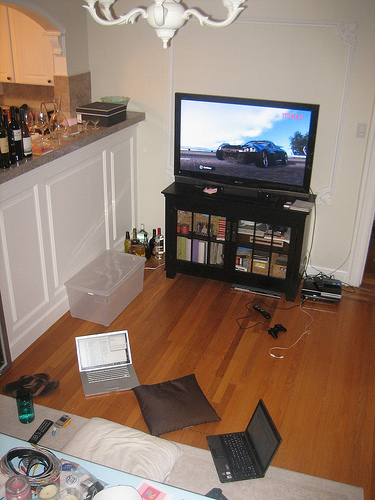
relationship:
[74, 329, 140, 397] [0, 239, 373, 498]
laptop on floor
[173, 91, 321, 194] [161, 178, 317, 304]
tv on stand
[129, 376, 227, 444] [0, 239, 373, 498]
pillow on floor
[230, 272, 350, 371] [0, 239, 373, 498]
machine on floor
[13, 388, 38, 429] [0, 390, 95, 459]
controller on carpet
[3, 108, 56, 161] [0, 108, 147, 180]
bottles on counter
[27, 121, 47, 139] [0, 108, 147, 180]
glasses on counter